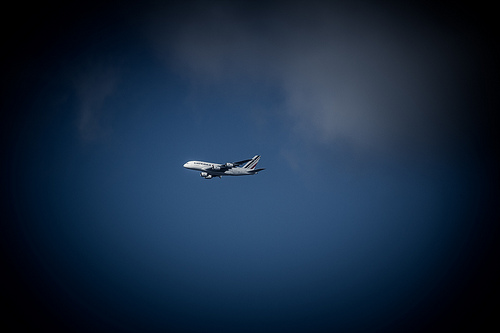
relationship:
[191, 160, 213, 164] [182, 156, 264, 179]
lateral windows of airplane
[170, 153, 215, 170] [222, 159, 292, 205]
windows on air plane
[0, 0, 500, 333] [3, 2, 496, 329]
cloud in sky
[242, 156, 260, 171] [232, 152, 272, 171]
stripes on tail fin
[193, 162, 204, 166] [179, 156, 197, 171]
windows of cockpit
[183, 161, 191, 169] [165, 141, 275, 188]
nose of airplane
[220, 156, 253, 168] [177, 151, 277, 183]
wing of airplane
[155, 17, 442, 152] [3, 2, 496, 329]
cloud in sky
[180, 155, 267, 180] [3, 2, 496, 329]
airplane in sky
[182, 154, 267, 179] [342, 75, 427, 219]
airplane in sky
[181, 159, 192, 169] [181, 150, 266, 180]
nose of airplane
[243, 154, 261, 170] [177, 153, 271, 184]
wing of airplane